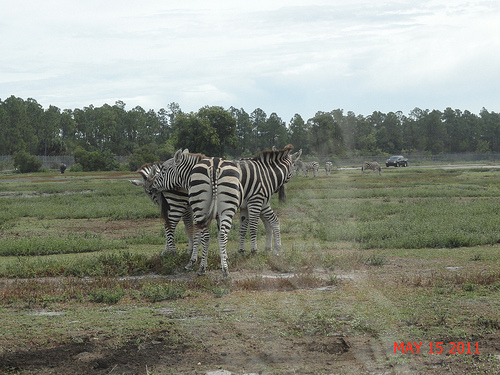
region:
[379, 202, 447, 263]
Grass on the ground.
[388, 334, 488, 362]
Watermark of the date.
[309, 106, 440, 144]
Trees in the background.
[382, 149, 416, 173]
A car in the background.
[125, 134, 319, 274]
Two zebras in a field.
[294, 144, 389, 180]
Animals in the distance.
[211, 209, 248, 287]
A zebra's hind leg.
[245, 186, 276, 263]
A zebra's front leg.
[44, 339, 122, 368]
Dirt on the ground.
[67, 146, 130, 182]
Vegetation in the background.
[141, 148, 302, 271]
the zebras standing together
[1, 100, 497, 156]
the tall row of trees with lots of green leaves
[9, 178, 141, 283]
patches of green grass are mixed in with dirt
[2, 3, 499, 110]
the blue sky above with white clouds mixed in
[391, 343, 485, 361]
the date stamp in the corner of the pic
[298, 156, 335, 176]
some more zebras standing around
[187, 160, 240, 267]
the back end of a zebra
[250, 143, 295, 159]
the striped mane of a zebra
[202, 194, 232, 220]
White hair on the end of zebra's tail.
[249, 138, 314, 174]
Zebra has black and white mane.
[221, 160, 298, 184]
Zebra is black and white.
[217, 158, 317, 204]
Zebra is covered in stripes.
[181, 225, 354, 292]
Zebra is standing in grassy field.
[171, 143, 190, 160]
Zebra has white ears.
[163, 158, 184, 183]
Zebra is covered in stripes.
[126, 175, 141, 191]
Zebra has white ear.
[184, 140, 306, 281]
black and white zebra standing in field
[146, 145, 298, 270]
black and white zebra standing between two zebras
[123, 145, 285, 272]
black and white striped zebra standing behind two other zebras in field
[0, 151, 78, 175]
fence on the edge of field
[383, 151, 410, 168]
car parked on edge of field of zebras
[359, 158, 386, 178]
zebra standing on field near car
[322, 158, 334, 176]
zebra standing in field near car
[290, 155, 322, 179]
zebra standing in field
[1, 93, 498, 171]
line of green trees surrounding large grassy field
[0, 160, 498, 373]
large flat open green grassy field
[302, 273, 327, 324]
part of a ground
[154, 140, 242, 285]
A zebra in a field.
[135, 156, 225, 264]
A zebra in a field.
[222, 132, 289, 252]
A zebra in a field.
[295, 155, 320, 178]
A zebra in a field.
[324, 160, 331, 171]
A zebra in a field.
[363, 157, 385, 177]
A zebra in a field.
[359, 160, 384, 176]
An animal in a field.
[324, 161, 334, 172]
An animal in a field.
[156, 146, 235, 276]
a zebra in a field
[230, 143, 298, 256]
a zebra in a field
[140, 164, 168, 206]
a zebra in a field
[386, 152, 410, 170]
a car in a parking lot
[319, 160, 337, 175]
a zebra in a field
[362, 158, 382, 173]
a zebra in a field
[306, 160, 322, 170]
a zebra in a field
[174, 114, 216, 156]
a tree in a field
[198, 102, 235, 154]
a tree in a field